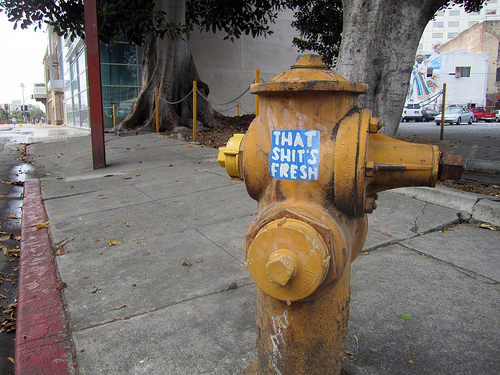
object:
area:
[0, 108, 498, 375]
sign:
[270, 129, 321, 181]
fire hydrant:
[216, 54, 466, 375]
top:
[250, 53, 369, 94]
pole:
[82, 1, 106, 171]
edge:
[13, 144, 77, 374]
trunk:
[111, 1, 221, 131]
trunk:
[334, 0, 446, 148]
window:
[98, 36, 144, 129]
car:
[434, 104, 475, 125]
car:
[470, 107, 496, 122]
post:
[113, 104, 117, 127]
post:
[155, 87, 159, 134]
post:
[193, 81, 197, 142]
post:
[255, 69, 260, 117]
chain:
[158, 89, 193, 104]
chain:
[195, 86, 250, 105]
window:
[59, 48, 94, 131]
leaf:
[122, 221, 130, 227]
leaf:
[107, 238, 122, 246]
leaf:
[36, 220, 57, 229]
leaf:
[182, 258, 193, 267]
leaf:
[91, 283, 98, 294]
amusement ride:
[405, 52, 442, 107]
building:
[30, 7, 334, 130]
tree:
[0, 0, 285, 131]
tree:
[270, 0, 485, 140]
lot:
[366, 133, 467, 196]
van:
[402, 101, 423, 122]